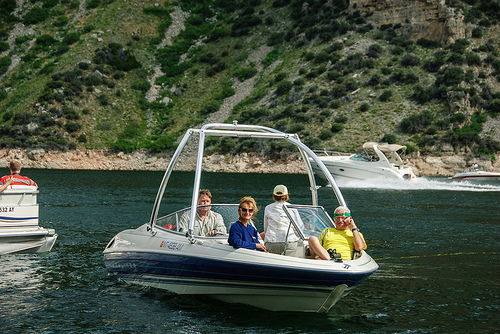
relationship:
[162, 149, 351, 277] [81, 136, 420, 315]
people in boat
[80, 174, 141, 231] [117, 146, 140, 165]
water and rock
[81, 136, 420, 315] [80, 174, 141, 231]
boat in water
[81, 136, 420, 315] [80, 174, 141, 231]
boat on water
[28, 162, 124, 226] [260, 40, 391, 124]
river in hill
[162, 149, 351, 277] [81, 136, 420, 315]
people on boat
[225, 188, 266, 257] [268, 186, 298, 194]
woman wear cap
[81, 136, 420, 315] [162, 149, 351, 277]
boat carrie people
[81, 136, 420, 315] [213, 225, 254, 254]
boat has bar